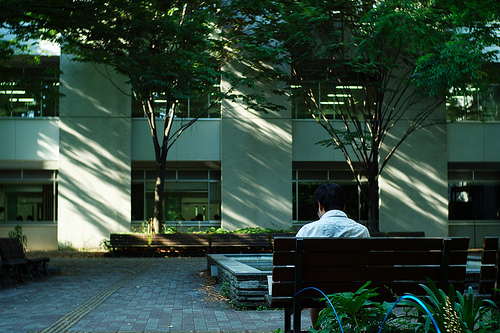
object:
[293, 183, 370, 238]
man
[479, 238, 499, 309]
bench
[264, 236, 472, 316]
bench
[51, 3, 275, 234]
tree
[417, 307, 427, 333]
leg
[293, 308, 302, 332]
leg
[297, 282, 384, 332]
plant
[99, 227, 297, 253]
plant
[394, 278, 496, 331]
plant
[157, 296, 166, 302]
brick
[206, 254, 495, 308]
brown bench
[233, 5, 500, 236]
trees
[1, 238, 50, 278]
bench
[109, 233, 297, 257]
bench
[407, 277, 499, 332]
plants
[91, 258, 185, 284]
ground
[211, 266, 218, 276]
box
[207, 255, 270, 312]
stone wall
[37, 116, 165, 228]
sun above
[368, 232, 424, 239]
bench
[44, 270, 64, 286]
pavement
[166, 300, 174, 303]
brick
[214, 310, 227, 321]
brick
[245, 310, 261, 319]
brick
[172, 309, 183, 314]
brick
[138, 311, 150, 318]
brick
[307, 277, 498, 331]
tropical plants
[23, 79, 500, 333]
foreground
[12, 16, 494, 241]
wall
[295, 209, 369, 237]
shirt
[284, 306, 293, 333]
front leg